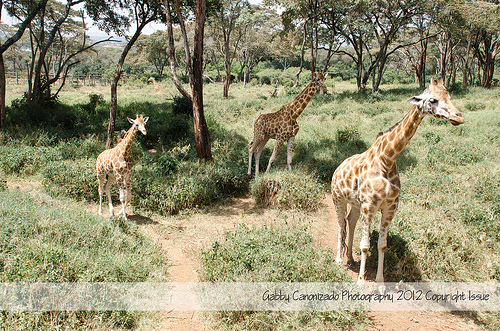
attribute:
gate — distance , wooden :
[5, 68, 95, 85]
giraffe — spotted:
[243, 67, 328, 179]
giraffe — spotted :
[92, 113, 149, 221]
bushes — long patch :
[155, 136, 235, 221]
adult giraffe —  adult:
[248, 70, 328, 181]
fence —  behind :
[0, 47, 121, 97]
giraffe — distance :
[146, 75, 163, 94]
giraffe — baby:
[327, 80, 481, 290]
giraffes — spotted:
[331, 76, 470, 283]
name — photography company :
[230, 282, 493, 319]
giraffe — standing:
[351, 100, 438, 262]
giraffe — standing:
[243, 82, 310, 157]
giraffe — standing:
[96, 111, 145, 193]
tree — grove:
[172, 20, 217, 151]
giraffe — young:
[288, 52, 485, 283]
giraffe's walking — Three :
[92, 63, 469, 300]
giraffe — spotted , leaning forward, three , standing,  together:
[329, 75, 466, 297]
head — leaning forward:
[420, 75, 465, 127]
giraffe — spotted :
[244, 69, 335, 176]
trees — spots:
[3, 8, 487, 125]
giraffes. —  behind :
[93, 66, 465, 287]